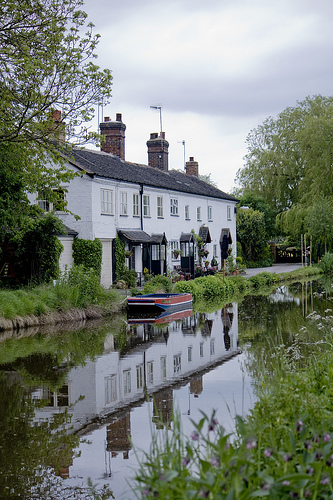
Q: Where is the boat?
A: In the river, parked next to the building.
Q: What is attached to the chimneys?
A: Old tv antennas.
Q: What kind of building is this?
A: Row houses.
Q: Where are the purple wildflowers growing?
A: Near the water.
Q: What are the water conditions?
A: Calm, like glass.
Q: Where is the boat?
A: In the water.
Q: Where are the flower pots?
A: In front of the house.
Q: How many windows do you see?
A: 12.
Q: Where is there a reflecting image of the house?
A: In the water.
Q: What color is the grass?
A: Green.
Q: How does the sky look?
A: Overcast.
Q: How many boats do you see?
A: 1.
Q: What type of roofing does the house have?
A: Shingles.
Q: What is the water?
A: Visible.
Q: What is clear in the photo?
A: Water.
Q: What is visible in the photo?
A: Water.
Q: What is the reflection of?
A: House.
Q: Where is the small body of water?
A: In front of house.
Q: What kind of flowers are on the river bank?
A: Purple.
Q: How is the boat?
A: The water.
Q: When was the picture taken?
A: DAytime.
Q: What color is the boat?
A: Red and blue.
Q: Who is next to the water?
A: A building.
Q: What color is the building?
A: White.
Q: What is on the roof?
A: Rocks.